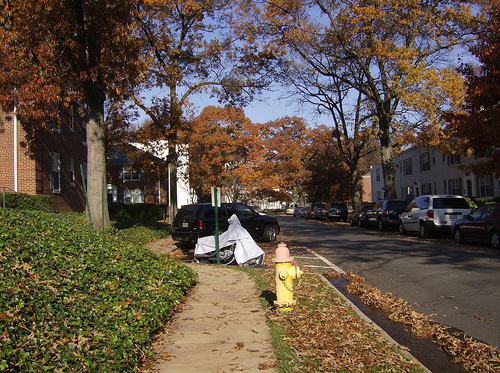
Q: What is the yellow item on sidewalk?
A: Fire hydrant.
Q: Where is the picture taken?
A: A street.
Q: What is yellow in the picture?
A: A hydrant.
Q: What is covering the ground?
A: Grass.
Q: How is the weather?
A: Clear.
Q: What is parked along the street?
A: Cars.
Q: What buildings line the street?
A: Homes.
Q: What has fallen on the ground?
A: Leaves.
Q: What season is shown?
A: Fall.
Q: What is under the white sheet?
A: A motorcycle.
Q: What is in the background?
A: Trees.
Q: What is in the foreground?
A: A yellow fire hydrant.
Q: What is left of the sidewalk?
A: Shrubs.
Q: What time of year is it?
A: Autumn.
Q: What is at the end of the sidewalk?
A: A sign.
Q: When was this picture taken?
A: During the day.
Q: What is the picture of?
A: A neighborhood.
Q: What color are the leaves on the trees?
A: Orange.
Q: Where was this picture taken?
A: Outside.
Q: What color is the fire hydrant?
A: Red and yellow.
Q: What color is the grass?
A: Green.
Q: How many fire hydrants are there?
A: One.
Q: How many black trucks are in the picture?
A: One.